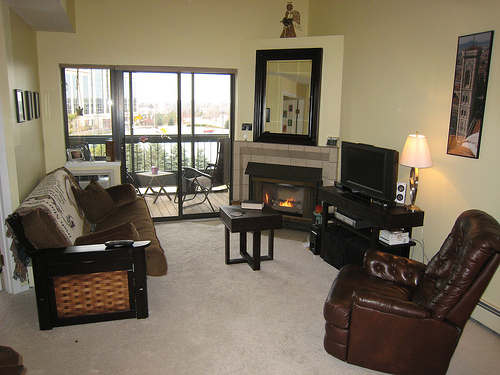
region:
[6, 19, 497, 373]
a family room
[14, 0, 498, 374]
a family room with a fireplace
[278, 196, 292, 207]
fire in the fireplace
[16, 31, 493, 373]
a carpeted room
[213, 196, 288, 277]
a small table in front of the tv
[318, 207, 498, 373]
a brown leather chair in the room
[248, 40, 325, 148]
a mirror on top of the mantle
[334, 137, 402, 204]
a television in the room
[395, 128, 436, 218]
a lampshade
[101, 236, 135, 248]
a remote control on the armrest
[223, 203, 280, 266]
dark brown coffee table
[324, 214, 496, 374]
brown leather reclining chair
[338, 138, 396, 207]
flat panel tv on stand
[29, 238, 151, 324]
brown and tan end table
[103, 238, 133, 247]
black remote control on table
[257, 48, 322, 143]
black mirror on wall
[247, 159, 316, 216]
lit wall fire place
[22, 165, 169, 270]
brown fabric sofa with blanket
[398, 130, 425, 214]
table lamp on stand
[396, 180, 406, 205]
silver speakers on stand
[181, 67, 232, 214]
This is a door pane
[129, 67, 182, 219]
This is a door pane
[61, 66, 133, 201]
This is a door pane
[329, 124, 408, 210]
This is a TV set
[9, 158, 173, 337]
This is a couch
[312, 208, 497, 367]
This is a couch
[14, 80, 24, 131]
This is a picture flame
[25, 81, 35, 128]
This is a picture flame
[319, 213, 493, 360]
A brown leather seat in the room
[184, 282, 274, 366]
The carpet is white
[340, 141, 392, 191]
A black TV in the room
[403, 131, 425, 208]
A bright lamp by the TV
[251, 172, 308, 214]
A fireplace in the room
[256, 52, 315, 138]
A mirror in the room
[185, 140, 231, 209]
One chair on the balcony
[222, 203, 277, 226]
The tabletop is black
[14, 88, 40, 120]
Three picture frames on the wall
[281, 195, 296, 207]
Flames in the fireplace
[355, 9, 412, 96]
this is the wall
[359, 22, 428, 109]
the wall is white in color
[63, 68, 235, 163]
this is a door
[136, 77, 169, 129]
the door is made of glass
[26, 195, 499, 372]
these are the couches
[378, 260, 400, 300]
the couch is brown in color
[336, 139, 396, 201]
this is a TV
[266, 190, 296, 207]
this is some fire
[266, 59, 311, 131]
this is a mirror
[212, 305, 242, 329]
the carpet is white in color